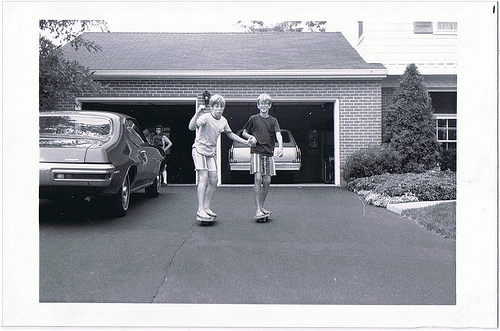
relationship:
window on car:
[37, 112, 115, 152] [39, 103, 174, 218]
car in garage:
[225, 124, 305, 173] [53, 68, 377, 184]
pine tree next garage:
[380, 63, 443, 171] [39, 32, 389, 187]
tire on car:
[108, 169, 140, 215] [39, 109, 164, 213]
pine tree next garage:
[377, 51, 449, 175] [48, 20, 393, 192]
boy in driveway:
[179, 88, 239, 237] [41, 162, 464, 323]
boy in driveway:
[234, 85, 296, 231] [41, 162, 464, 323]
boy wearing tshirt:
[188, 94, 256, 219] [189, 116, 230, 151]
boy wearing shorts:
[188, 94, 256, 219] [173, 136, 225, 179]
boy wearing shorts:
[188, 94, 256, 219] [178, 141, 218, 181]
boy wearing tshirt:
[188, 94, 256, 219] [186, 117, 221, 149]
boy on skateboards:
[188, 94, 256, 219] [196, 206, 224, 231]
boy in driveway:
[188, 94, 256, 219] [45, 167, 460, 307]